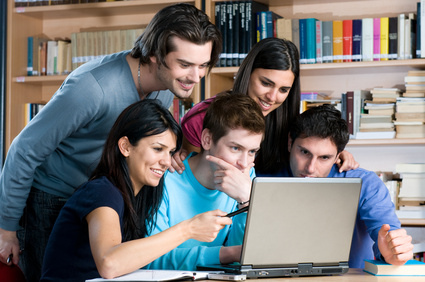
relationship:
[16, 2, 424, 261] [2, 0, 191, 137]
books on bookshelf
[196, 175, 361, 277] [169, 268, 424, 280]
laptop on table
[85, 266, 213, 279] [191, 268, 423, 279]
book on table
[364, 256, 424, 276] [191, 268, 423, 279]
book on table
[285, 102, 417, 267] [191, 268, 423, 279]
person at table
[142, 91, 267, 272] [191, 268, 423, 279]
man at table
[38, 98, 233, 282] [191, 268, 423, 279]
lady at table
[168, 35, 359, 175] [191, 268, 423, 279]
lady at table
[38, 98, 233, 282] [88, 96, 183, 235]
lady has hair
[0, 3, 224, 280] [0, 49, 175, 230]
man wearing shirt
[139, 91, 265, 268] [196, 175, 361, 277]
man in front of laptop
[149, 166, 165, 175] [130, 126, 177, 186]
smile on face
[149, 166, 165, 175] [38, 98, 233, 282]
smile on lady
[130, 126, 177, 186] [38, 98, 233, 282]
face on lady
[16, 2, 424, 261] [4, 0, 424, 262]
books on bookshelf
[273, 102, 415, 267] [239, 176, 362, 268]
person staring at computer screen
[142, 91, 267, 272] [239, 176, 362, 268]
man staring at computer screen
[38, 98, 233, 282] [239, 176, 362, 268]
lady staring at computer screen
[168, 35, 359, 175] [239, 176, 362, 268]
lady staring at computer screen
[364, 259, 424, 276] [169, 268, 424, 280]
book on table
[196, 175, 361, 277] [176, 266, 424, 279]
laptop on table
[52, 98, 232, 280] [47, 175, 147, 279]
lady wearing shirt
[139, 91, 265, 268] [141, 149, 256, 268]
man wearing shirt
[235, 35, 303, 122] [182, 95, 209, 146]
lady in a pink shirt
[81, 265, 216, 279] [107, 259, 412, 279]
open book on table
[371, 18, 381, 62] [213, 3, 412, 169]
pink book on shelf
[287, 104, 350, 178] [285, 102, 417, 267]
head of a person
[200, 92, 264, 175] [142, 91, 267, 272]
head of a man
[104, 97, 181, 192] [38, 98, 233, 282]
head of a lady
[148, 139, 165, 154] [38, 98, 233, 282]
eye of a lady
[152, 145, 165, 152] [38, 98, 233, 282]
eye of a lady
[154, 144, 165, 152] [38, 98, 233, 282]
eye of a lady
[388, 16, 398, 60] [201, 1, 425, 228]
book on bookcase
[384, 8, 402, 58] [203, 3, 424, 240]
book inside of bookcase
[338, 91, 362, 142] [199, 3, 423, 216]
book inside of bookcase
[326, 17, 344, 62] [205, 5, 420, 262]
book inside of bookcase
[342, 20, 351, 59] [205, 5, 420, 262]
book inside of bookcase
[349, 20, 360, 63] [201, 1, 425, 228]
book inside of bookcase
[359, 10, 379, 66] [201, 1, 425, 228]
book inside of bookcase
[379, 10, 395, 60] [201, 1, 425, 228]
book inside of bookcase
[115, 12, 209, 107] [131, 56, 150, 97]
man wearing necklace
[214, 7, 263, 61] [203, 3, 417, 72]
set on top of shelf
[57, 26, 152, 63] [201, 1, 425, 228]
set on top of bookcase